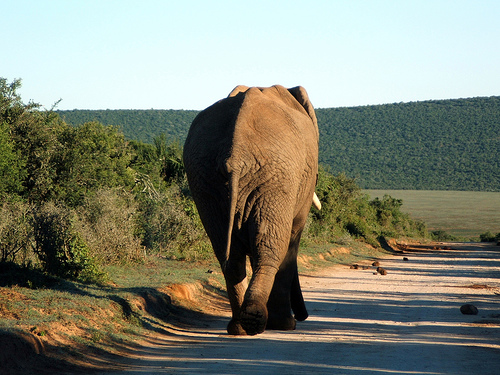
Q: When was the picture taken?
A: Daytime.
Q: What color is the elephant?
A: Gray.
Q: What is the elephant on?
A: Dirt.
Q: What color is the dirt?
A: Brown.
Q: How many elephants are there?
A: One.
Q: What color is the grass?
A: Green.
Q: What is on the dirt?
A: The elephant.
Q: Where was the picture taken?
A: Road.